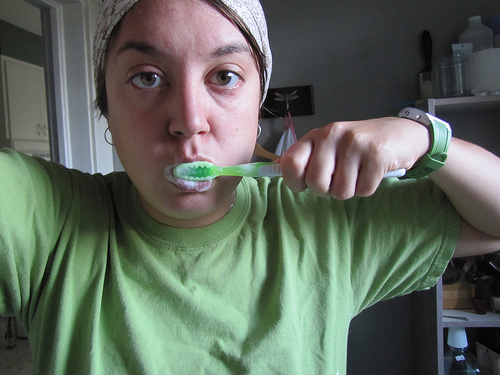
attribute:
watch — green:
[381, 103, 455, 204]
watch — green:
[392, 106, 451, 177]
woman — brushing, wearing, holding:
[1, 0, 498, 372]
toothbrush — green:
[148, 143, 335, 218]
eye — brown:
[123, 62, 168, 89]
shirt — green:
[2, 153, 449, 371]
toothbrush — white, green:
[178, 161, 408, 181]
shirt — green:
[39, 164, 389, 352]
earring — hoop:
[103, 126, 116, 146]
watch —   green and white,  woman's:
[396, 104, 454, 181]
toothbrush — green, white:
[166, 160, 406, 188]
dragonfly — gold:
[272, 86, 301, 108]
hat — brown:
[92, 0, 273, 101]